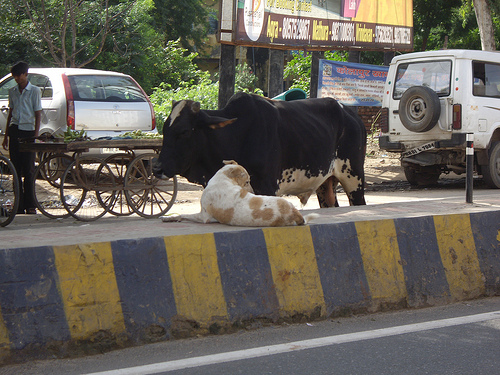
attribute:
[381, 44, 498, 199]
truck — White 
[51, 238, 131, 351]
stripe — yellow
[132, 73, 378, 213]
cow — black, white , big 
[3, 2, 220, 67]
trees — tall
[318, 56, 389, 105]
sign — blue , red 